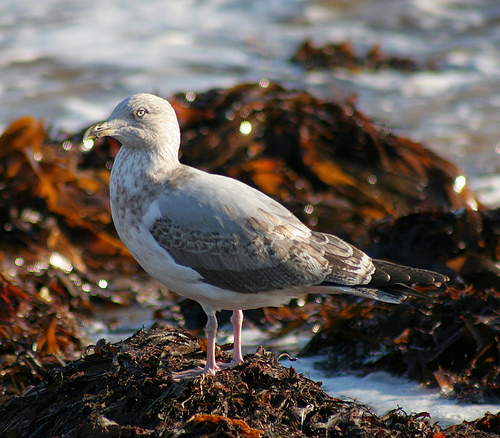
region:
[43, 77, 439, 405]
a gray pigeon perched on wet leaves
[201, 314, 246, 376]
pink legs supporting a body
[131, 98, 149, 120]
a silver eye looking at the camera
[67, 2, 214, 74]
a river behind the bird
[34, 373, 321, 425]
a mound of wet dark leaves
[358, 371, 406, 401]
white foam from the water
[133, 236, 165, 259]
white feathers on the chest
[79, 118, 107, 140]
a pale yellow beak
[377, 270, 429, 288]
black tail feathers sticking out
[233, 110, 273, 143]
sunlight reflection on the wet surface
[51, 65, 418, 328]
one bird in photo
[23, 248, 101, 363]
leaves on the ground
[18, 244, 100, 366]
orange leaves in photo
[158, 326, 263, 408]
talons of the bird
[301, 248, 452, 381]
tail feather of the bird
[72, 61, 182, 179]
head of the bird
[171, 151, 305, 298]
feathers of the bird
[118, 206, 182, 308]
white part of bird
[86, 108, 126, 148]
beak of a bird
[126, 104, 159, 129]
eye of bird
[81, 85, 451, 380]
The bird in the photo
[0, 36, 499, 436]
The seaweed around the grey bird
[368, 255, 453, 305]
The black portion of the bird's tail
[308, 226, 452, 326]
The tail of the bird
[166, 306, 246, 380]
The legs of the bird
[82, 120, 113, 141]
The beak of the bird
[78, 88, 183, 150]
The head of the bird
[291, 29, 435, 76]
The small pile of seaweed separated from the others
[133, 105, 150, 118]
The eye of the bird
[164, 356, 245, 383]
The bird's webbed feet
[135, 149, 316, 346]
gray feathers on bird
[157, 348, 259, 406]
talons of bird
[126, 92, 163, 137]
eye of the bird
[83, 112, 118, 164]
beak on the bird's head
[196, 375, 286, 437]
dirt and leaves under bird's feet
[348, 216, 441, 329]
tail feather of bird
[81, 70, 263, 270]
white and gray bird looking to left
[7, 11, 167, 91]
blurry background of photo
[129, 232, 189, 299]
white portion of bird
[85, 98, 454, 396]
Seagull standing on rocks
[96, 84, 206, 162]
Seagulls head is white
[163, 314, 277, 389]
Seagull's feet and legs are pink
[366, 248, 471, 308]
Seagull's tail is black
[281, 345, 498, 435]
Seawater behind seagull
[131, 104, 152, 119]
Seagull's eye is yellow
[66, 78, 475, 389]
Seagull stands resolute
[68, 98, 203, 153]
Seagull's head is small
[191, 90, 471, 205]
Mound is wet and orange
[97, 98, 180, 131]
Seagull is not blinking